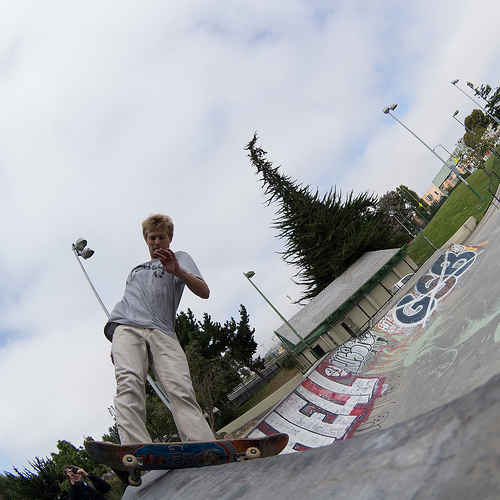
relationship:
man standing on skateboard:
[98, 206, 232, 442] [75, 430, 295, 487]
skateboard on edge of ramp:
[84, 429, 288, 488] [123, 183, 498, 497]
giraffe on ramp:
[77, 427, 302, 488] [139, 239, 498, 499]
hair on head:
[142, 215, 173, 234] [142, 212, 174, 259]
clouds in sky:
[8, 16, 65, 68] [2, 3, 497, 483]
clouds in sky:
[0, 0, 499, 472] [164, 39, 434, 131]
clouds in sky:
[0, 0, 499, 472] [5, 10, 373, 194]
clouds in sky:
[0, 0, 499, 472] [2, 3, 497, 483]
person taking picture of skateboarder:
[57, 461, 117, 498] [103, 208, 220, 443]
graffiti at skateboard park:
[250, 309, 441, 476] [110, 148, 493, 498]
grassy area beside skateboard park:
[398, 144, 498, 267] [104, 193, 497, 498]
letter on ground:
[430, 248, 478, 277] [125, 217, 497, 494]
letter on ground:
[408, 272, 460, 298] [125, 217, 497, 494]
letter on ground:
[388, 292, 441, 325] [125, 217, 497, 494]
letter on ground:
[300, 367, 383, 397] [125, 217, 497, 494]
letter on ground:
[268, 390, 362, 441] [125, 217, 497, 494]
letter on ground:
[430, 223, 462, 291] [121, 180, 497, 497]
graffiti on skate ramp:
[256, 309, 441, 476] [236, 245, 497, 479]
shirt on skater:
[104, 248, 204, 338] [105, 210, 220, 443]